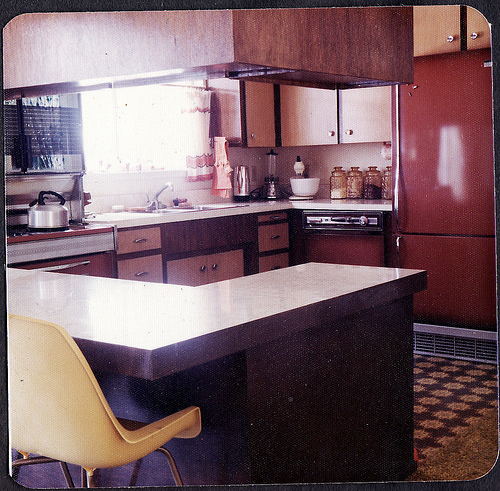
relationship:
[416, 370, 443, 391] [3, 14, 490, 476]
tile in kitchen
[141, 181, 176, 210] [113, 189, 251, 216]
faucet over sink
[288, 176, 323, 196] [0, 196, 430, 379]
bowl on counter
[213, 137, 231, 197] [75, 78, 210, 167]
dish towel beside window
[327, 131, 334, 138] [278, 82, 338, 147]
knob on cabinet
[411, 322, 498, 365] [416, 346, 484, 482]
vent built on top of floor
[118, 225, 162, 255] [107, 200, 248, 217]
drawer built under sink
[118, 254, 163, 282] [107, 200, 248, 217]
drawer built under sink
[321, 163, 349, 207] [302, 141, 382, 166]
jar pushed against wall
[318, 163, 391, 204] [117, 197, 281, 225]
container counter on counter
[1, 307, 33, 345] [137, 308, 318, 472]
chair under counter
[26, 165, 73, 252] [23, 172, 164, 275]
kettle on stove